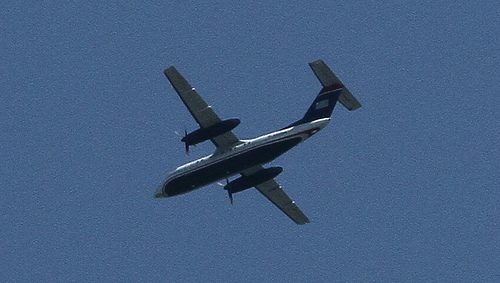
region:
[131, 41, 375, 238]
a plane in the blue sky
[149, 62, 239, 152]
left wing of a plane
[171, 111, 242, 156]
a engine under a wing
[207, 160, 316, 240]
a engine on the right side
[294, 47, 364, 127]
vertical stabilizer of plane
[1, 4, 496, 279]
plane is flying in a blue sky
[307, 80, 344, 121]
part of the vertical stabilizer that is blue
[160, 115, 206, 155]
a helice a propeller on left engine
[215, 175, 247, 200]
a helice a propeller on right engine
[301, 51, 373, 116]
a horizontal stabilizer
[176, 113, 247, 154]
Left motor of airplane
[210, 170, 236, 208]
Right motor of airplane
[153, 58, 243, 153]
Left wing of airplane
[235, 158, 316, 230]
Right wing of airplane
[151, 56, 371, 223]
Airplane flying in the air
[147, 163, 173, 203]
Nose of airplane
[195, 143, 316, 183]
Belly of airplane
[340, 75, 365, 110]
Right elevator of airplane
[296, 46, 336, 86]
Left elevator of airplane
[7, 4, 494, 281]
Blue sky airplane is flying through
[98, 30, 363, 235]
large white and blue plane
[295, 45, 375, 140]
white tail of a plane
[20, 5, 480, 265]
blue sky with no clouds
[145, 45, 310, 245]
long white wings of a plane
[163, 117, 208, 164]
small plane propellor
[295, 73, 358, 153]
red and blue design on plane tail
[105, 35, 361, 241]
plane with two long wings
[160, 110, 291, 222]
two small propellors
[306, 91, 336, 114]
small white square on tail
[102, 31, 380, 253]
plane flying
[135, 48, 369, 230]
black and silver plane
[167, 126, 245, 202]
silver propellers on engines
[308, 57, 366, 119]
silver tail fin on plane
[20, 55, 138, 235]
clear dark blue sky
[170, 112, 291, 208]
plane has two engines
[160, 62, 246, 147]
left wing of plane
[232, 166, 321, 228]
right wing of plane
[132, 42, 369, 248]
plane flying in clear blue sky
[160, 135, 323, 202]
black underbelly of plane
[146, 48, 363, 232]
commercial airplane in sky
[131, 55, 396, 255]
the airplane in the sky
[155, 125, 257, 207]
the propellers of the air plane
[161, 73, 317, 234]
the two wins of the airplane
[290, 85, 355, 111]
the us airways logo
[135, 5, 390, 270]
the airplane that is flying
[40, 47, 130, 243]
nice clear blue skies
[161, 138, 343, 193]
the bottom of the airplane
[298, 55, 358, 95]
the back wing of the plane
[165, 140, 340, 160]
the side of the airplae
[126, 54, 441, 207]
welcome to US airways